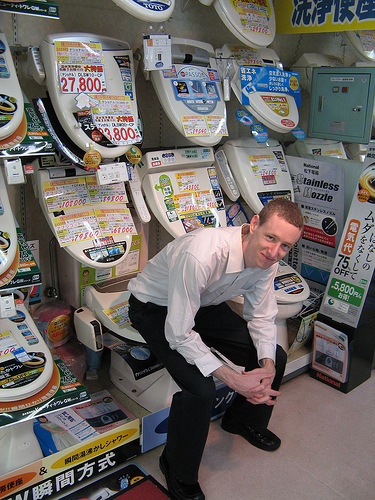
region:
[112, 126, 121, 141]
The number is red.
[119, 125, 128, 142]
The number is red.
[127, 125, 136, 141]
The number is red.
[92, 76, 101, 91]
The number is red.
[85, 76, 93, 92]
The number is red.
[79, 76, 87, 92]
The number is red.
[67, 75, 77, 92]
The number is red.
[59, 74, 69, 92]
The number is red.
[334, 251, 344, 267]
The number is black.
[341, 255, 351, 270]
The number is black.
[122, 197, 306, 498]
man sitting on toilet seat in shop display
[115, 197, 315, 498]
young man sitting with hands folded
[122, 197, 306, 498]
young man wearing white shirt and black pants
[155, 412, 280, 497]
black dress shoes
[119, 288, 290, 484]
men's black dress pants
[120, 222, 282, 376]
white long-sleeved dress shirt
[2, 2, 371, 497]
a display of toilet seats in a store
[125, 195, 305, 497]
a man with light brown hair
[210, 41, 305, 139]
a toilet seat with blue, yellow, and red tags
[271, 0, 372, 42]
a yellow sign with blue lettering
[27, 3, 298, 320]
numerous toilet seats on wall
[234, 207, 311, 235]
boy has short hair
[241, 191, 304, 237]
boy has dark hair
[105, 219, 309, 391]
boy has white shirt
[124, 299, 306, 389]
boy has black pants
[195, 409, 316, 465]
boy has black shoes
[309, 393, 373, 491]
floor is light brown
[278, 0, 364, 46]
yellow and blue sign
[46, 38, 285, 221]
prices listed on signs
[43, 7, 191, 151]
grey wall behind toilet seats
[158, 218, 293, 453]
this is a man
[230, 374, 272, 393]
the man is light skinned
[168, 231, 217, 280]
this is a shirt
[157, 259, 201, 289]
the shirt is white in color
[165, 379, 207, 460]
this is a trouser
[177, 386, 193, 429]
the trouser is black in color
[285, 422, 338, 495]
this is the floor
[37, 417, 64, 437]
this is a lady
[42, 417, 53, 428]
the lady is light skinned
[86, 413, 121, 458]
this is a box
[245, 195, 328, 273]
a man with short hair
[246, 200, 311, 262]
a man with red hair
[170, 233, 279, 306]
a man wearing white shirt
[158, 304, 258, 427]
a man wearing black pants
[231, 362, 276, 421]
a man with his hands together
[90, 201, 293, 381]
a man sitting on a toilet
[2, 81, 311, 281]
several toilets hanging on a wall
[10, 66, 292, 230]
several toilets on a wall for display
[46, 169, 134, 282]
a toilet with several stickers on it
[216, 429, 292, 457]
a man wearing black shoes